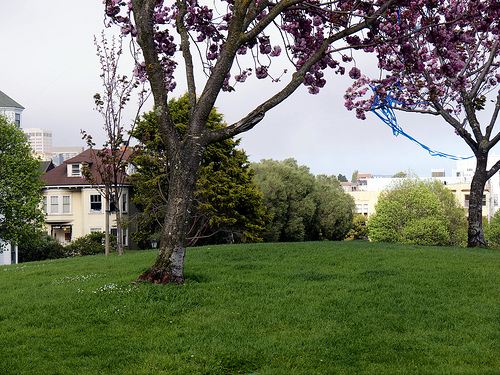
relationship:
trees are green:
[234, 141, 343, 241] [287, 189, 321, 223]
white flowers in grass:
[89, 281, 141, 302] [94, 297, 113, 314]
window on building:
[88, 191, 105, 215] [33, 141, 138, 251]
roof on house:
[39, 148, 138, 188] [39, 142, 139, 249]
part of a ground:
[285, 242, 332, 300] [8, 237, 480, 363]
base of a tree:
[129, 247, 194, 287] [93, 3, 406, 283]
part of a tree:
[463, 209, 483, 246] [342, 13, 484, 246]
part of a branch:
[222, 96, 264, 145] [200, 6, 370, 141]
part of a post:
[100, 220, 127, 253] [77, 26, 148, 259]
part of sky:
[303, 125, 352, 175] [3, 8, 468, 168]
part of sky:
[340, 122, 388, 162] [3, 8, 468, 168]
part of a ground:
[262, 309, 319, 368] [8, 237, 480, 363]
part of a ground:
[294, 244, 336, 278] [8, 237, 480, 363]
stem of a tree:
[145, 172, 208, 270] [93, 3, 406, 283]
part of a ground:
[341, 278, 401, 331] [8, 237, 480, 363]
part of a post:
[99, 243, 105, 251] [100, 230, 107, 252]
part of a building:
[355, 180, 369, 191] [338, 174, 436, 242]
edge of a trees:
[315, 177, 354, 237] [234, 156, 357, 244]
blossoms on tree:
[100, 7, 387, 96] [120, 6, 399, 283]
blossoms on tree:
[340, 3, 466, 119] [342, 13, 484, 246]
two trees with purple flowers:
[102, 19, 498, 273] [343, 74, 383, 119]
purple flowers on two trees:
[346, 66, 376, 130] [91, 0, 490, 294]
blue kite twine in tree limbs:
[365, 82, 444, 176] [370, 74, 436, 116]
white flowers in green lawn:
[77, 267, 151, 321] [0, 242, 499, 374]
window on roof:
[66, 158, 85, 179] [30, 148, 148, 185]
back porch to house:
[44, 219, 71, 246] [31, 117, 181, 267]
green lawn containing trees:
[14, 240, 493, 351] [108, 3, 338, 293]